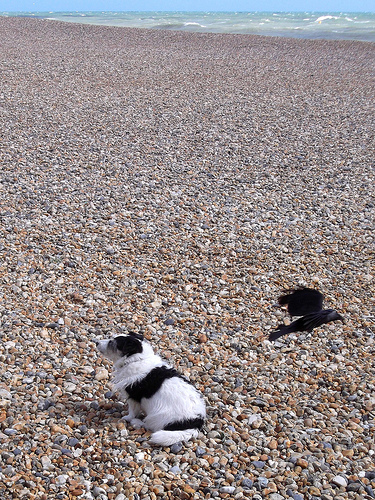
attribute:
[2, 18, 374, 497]
stones — small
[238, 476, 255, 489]
rock — gray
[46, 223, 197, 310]
stones — small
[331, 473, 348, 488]
rock — white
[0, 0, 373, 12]
sky — clear, blue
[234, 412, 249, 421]
rock — brown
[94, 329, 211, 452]
dog — white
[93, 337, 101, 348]
nose — grey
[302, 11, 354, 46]
wave — white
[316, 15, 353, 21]
cap wave — white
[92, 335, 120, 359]
face — white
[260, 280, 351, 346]
bird — black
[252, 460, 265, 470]
rock — small, gray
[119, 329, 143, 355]
ears — black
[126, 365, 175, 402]
stripe — black